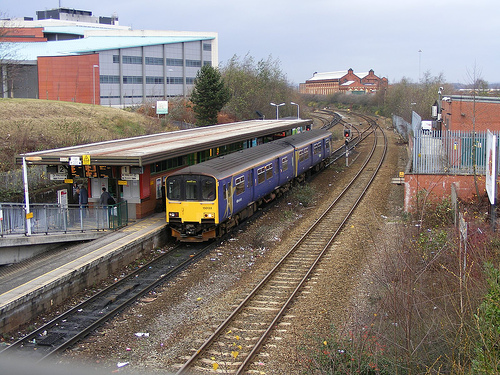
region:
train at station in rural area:
[53, 100, 388, 272]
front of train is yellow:
[156, 165, 236, 251]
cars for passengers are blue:
[190, 132, 346, 233]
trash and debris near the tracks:
[18, 227, 277, 361]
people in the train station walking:
[53, 175, 128, 222]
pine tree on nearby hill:
[183, 56, 240, 118]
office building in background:
[10, 0, 231, 108]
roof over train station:
[24, 117, 304, 169]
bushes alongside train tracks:
[371, 170, 491, 362]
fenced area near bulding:
[381, 96, 481, 186]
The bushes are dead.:
[370, 228, 497, 365]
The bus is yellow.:
[146, 159, 271, 271]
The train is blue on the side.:
[185, 155, 431, 247]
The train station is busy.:
[18, 122, 382, 232]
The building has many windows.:
[27, 10, 228, 135]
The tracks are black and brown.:
[80, 257, 292, 369]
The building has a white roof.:
[300, 51, 403, 98]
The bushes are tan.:
[10, 101, 126, 149]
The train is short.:
[153, 123, 406, 251]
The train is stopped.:
[148, 107, 342, 254]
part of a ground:
[309, 279, 347, 350]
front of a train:
[152, 180, 214, 242]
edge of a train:
[266, 318, 278, 342]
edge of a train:
[210, 190, 225, 226]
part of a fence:
[81, 212, 98, 225]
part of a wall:
[132, 180, 144, 207]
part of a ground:
[303, 298, 327, 340]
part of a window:
[173, 174, 203, 199]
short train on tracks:
[145, 128, 349, 243]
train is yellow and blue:
[158, 121, 352, 253]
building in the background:
[1, 1, 254, 119]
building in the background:
[293, 62, 393, 109]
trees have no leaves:
[358, 229, 461, 361]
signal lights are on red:
[274, 114, 361, 149]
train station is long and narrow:
[33, 92, 320, 249]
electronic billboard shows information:
[53, 158, 138, 183]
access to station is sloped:
[2, 190, 139, 282]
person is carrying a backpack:
[93, 181, 120, 220]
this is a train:
[176, 138, 288, 235]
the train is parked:
[167, 160, 254, 215]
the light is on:
[205, 212, 215, 217]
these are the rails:
[104, 280, 305, 348]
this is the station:
[116, 147, 160, 216]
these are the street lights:
[268, 94, 301, 113]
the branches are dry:
[371, 264, 459, 324]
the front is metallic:
[186, 222, 206, 240]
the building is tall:
[87, 42, 187, 102]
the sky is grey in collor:
[337, 20, 392, 45]